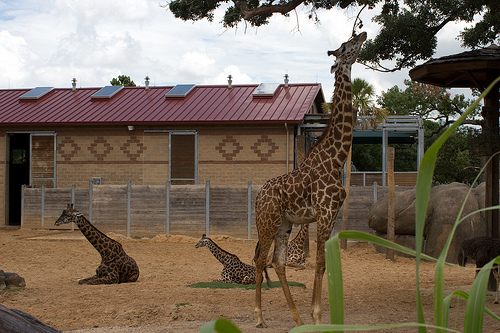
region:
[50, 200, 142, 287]
a giraffe sitting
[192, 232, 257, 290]
a giraffe on the ground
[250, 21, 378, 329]
a giraffe trying to eat the leaf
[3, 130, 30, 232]
a door of the building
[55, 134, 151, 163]
pattern on the wall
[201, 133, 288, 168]
pattern on the wall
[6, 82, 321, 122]
a roof of the building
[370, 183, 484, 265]
a big rock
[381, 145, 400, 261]
a post on the ground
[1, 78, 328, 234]
a building in the background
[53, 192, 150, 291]
A medium sized giraffe on the ground.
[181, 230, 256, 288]
A small giraffe on the ground.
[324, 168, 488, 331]
Several leaves stick up from the ground.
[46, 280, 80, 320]
The dirt is light brown.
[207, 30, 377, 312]
A large giraffe reaching for some food.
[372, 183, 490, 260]
A large boulder in the enclosure.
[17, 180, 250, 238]
A large wooden fence.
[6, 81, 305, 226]
A large building in the background.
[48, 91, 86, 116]
The building has a red shingled roof.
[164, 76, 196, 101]
Solar panels on top of the roof.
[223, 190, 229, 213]
part of a fence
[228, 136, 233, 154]
part of a house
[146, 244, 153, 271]
edge of a roof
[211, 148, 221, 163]
side of a house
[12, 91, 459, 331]
a giraffe pen at the zoo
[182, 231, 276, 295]
a little giraffe lying in a patch of grass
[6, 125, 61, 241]
the door to giraffe enclosure so the can get out of the weather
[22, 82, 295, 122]
solar panels on top of giraffe building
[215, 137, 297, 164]
the diamond shape design on building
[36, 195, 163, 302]
a giraffe lying in the dirt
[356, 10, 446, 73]
a tree for the giraffe to chew on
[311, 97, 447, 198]
a canopy over part of the building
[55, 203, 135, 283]
brown and tan spotted giraffe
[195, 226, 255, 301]
brown and tan spotted giraffe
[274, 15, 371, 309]
brown and tan spotted giraffe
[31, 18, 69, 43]
white clouds in blue sky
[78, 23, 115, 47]
white clouds in blue sky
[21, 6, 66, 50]
white clouds in blue sky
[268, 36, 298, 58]
white clouds in blue sky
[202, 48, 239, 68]
white clouds in blue sky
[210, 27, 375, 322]
giraffe grazing from a tree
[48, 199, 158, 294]
giraffe sitting on the ground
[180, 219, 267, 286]
small giraffe on the ground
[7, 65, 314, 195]
brown brick building with red roof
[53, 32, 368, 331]
giraffes inside the enclosure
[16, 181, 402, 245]
wooden wall behind giraffes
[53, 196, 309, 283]
giraffes laying in the sand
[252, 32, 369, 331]
giraffe standing and eating from a tree